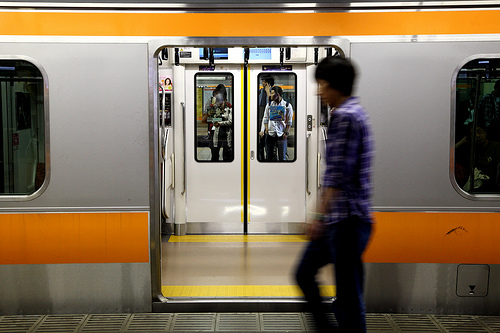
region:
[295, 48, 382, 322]
a man wearing a plaid shirt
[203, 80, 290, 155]
people standing on the other side of the door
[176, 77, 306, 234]
a white train door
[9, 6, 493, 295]
a silver and yellow train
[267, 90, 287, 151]
a man in a white shirt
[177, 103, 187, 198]
a silver handle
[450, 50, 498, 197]
a window in the train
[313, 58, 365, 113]
a man with dark hair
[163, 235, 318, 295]
the floor of the trian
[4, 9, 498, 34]
a yellow strip on the train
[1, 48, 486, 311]
this is a train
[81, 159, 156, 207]
the train is metallic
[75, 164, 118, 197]
the train is grey in color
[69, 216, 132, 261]
this is a strip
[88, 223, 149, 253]
the strip is yellow in color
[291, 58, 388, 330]
this is a man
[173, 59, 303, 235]
this is the door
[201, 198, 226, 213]
the door is white in color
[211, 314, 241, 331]
this is a pavement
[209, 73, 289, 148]
these are some passengers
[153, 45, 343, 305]
open train door in front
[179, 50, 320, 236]
closed train doors on other side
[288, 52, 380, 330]
blurry image of man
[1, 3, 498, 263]
orange stripes on silver train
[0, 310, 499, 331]
extended metal platform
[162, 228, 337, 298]
yellow lines on both sides of train floor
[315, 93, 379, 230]
blue and white plaid shirt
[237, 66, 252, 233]
yellow and black line between doors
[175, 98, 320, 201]
silver rails on sides of doors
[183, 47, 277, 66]
blue ads above doors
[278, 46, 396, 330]
A man in the foreground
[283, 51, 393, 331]
A side view of a man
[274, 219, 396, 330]
Man is wearing dark blue pants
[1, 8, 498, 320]
A subway train in the foreground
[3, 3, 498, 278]
Subway train has orange colored stripes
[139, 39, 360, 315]
Subway train door is open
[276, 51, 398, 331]
Person in the foreground is blurred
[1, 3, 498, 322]
Subway train's main color is gray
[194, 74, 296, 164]
People are inside of the window's view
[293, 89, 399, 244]
Man is wearing a blue shirt